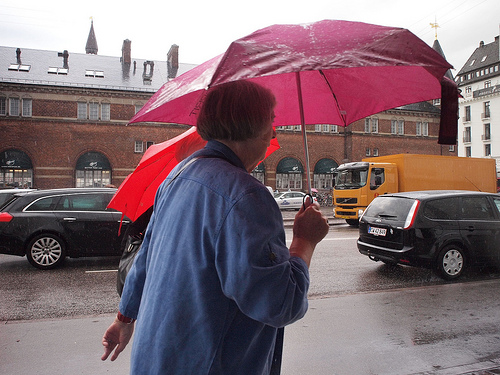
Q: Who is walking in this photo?
A: Two Women.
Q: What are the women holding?
A: Umbrellas.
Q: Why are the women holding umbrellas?
A: Because it is raining outside.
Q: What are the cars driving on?
A: A road.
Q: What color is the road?
A: Black.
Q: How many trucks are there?
A: One.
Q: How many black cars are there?
A: Two.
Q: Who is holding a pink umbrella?
A: Woman in blue coat.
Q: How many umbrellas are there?
A: 2.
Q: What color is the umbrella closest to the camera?
A: Pink.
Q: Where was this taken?
A: On a street.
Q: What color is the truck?
A: Yellow.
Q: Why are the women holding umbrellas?
A: Raining.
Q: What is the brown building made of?
A: Brick.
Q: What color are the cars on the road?
A: Black.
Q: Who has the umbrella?
A: The woman.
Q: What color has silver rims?
A: The black car.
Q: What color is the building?
A: Brown.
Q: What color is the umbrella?
A: Red.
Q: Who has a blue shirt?
A: The woman.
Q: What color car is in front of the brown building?
A: White.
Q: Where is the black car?
A: In front of the yellow truck.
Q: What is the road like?
A: Wet.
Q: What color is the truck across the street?
A: Yellow.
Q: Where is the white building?
A: To the right.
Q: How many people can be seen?
A: Two.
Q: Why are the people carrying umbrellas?
A: It's rainy.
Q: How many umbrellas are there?
A: Two.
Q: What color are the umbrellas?
A: Red and pink.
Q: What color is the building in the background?
A: Red.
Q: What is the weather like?
A: Rainy.